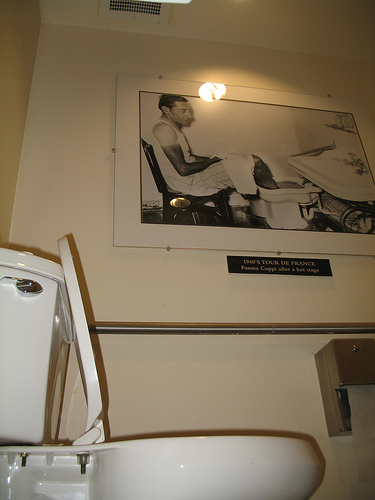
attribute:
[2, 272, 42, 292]
flusher handle — chrome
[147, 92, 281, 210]
athlete — soaking his feet, sitting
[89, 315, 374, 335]
metal bar — round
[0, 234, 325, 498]
clean toilet — white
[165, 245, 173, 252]
screw — small, gray, metal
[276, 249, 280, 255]
screw — small, gray, metal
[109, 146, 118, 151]
screw — small, gray, metal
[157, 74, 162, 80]
screw — small, gray, metal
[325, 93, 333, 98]
screw — small, gray, metal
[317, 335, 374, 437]
toilet paper — locked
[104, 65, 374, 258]
photograph — old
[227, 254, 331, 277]
sign — black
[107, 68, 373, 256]
poster — from the 1940s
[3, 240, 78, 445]
toilet tank — white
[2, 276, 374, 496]
toilet — white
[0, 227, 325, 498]
toilet — white, porcelain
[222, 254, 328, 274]
sign — black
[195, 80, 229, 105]
reflection — light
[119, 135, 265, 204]
chair — black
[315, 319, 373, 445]
dispenser — toilet paper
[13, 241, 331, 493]
toilet — white, brown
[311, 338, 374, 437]
shelf — wood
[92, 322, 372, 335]
railing — metal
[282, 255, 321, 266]
letters — golden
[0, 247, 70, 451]
tank — white